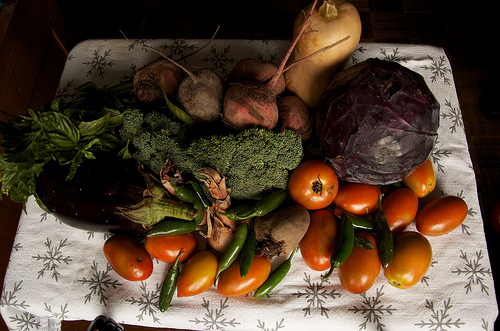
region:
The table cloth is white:
[8, 21, 492, 323]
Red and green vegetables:
[113, 175, 475, 304]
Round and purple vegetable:
[301, 45, 453, 188]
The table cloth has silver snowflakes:
[14, 18, 488, 327]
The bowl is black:
[29, 159, 175, 238]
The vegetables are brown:
[138, 42, 310, 137]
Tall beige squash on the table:
[276, 2, 364, 99]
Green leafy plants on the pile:
[22, 87, 302, 227]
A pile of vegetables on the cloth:
[52, 12, 458, 318]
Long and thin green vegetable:
[211, 216, 251, 292]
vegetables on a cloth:
[28, 11, 454, 280]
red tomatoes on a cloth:
[394, 181, 469, 286]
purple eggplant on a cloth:
[29, 159, 193, 242]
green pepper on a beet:
[231, 194, 288, 223]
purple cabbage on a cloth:
[314, 63, 444, 182]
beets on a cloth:
[216, 61, 291, 134]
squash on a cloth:
[284, 3, 379, 86]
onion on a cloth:
[199, 171, 236, 254]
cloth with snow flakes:
[334, 294, 461, 328]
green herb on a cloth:
[32, 90, 115, 159]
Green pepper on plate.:
[328, 214, 360, 279]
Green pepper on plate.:
[375, 196, 408, 293]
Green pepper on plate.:
[236, 228, 267, 287]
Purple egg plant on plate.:
[44, 133, 170, 229]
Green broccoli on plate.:
[208, 133, 303, 228]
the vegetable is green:
[188, 133, 313, 214]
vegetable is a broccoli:
[184, 133, 321, 199]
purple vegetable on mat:
[283, 52, 447, 179]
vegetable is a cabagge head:
[305, 53, 461, 205]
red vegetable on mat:
[299, 162, 479, 311]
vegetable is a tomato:
[280, 164, 495, 316]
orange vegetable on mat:
[280, 1, 380, 102]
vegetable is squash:
[273, 6, 375, 96]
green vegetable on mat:
[153, 242, 188, 312]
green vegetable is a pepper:
[125, 245, 222, 328]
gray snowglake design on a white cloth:
[27, 230, 70, 282]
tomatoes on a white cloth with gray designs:
[385, 179, 470, 291]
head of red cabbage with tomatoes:
[312, 59, 441, 207]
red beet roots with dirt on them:
[168, 56, 312, 130]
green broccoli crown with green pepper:
[178, 127, 302, 215]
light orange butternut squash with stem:
[281, 0, 361, 110]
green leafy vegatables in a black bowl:
[0, 105, 97, 198]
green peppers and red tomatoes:
[322, 180, 422, 287]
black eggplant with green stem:
[26, 156, 202, 232]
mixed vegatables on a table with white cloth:
[16, 39, 471, 299]